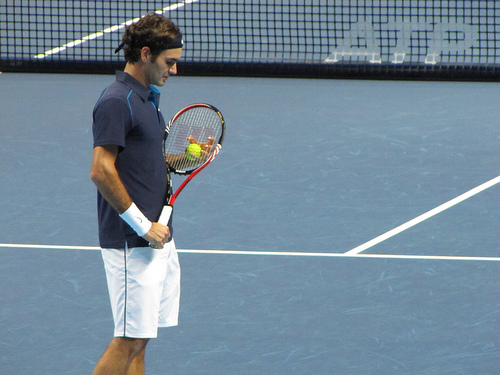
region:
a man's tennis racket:
[148, 105, 225, 248]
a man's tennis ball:
[187, 141, 204, 161]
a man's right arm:
[91, 150, 170, 245]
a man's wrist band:
[118, 200, 153, 238]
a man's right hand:
[147, 221, 172, 248]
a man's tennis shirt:
[92, 73, 176, 248]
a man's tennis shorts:
[97, 244, 180, 341]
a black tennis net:
[0, 0, 498, 74]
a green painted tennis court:
[2, 0, 498, 374]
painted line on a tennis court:
[3, 240, 498, 260]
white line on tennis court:
[346, 173, 497, 260]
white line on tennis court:
[2, 236, 499, 283]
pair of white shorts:
[95, 221, 195, 346]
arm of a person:
[84, 95, 174, 262]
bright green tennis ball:
[182, 136, 205, 166]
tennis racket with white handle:
[140, 100, 229, 230]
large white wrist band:
[117, 194, 157, 239]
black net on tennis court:
[0, 1, 498, 82]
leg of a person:
[87, 227, 169, 374]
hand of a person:
[135, 214, 175, 254]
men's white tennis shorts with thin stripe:
[101, 236, 182, 340]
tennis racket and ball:
[149, 102, 226, 249]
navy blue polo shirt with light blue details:
[92, 69, 174, 247]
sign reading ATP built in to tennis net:
[321, 18, 478, 67]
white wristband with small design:
[117, 200, 154, 237]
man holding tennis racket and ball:
[93, 11, 226, 373]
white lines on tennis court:
[0, 168, 499, 263]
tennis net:
[0, 0, 499, 83]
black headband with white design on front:
[115, 31, 184, 54]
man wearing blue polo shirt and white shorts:
[91, 10, 226, 373]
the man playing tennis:
[90, 12, 226, 373]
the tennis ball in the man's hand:
[183, 144, 201, 161]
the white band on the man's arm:
[117, 200, 150, 236]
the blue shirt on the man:
[92, 69, 174, 248]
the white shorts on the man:
[101, 237, 180, 338]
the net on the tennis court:
[0, 0, 499, 81]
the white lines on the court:
[0, 174, 498, 260]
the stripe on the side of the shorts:
[121, 247, 127, 337]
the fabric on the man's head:
[113, 31, 183, 54]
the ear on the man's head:
[140, 45, 149, 63]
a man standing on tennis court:
[69, 5, 229, 371]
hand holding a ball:
[174, 130, 216, 173]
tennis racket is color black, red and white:
[147, 100, 232, 238]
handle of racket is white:
[151, 200, 177, 247]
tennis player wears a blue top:
[71, 5, 215, 367]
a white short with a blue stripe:
[99, 245, 185, 344]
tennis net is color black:
[185, 5, 498, 87]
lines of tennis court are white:
[191, 160, 497, 302]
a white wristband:
[113, 192, 154, 247]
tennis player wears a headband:
[77, 8, 207, 146]